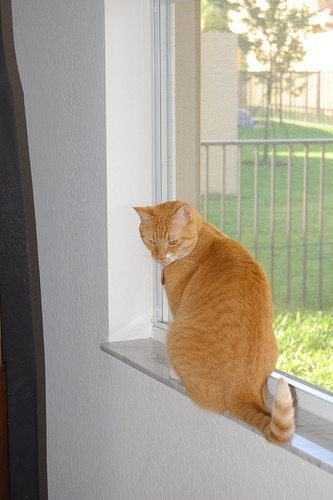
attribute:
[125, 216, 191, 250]
eyes — pair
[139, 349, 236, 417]
window sill — gray, marble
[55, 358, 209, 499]
walls — white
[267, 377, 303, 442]
tail — tan, white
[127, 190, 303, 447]
cat — looking grumpy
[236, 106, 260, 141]
grill — small, black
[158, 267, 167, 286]
collar — red tag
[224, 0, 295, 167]
tree — skinny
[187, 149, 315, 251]
fence — silver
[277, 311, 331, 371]
green grass — filled with sunlight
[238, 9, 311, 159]
tree — small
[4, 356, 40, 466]
bedpost — pictured